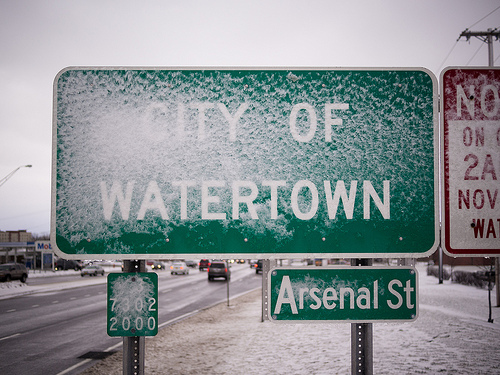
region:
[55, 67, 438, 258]
Snow on the sign.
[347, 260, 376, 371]
Metal post on the ground.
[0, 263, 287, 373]
Paved roads on the ground.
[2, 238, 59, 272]
Gas station in the background.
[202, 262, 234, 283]
Car on the road.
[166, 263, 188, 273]
Red taillights on the car.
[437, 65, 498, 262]
Street sign by the road.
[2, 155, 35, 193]
Light over the street.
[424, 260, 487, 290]
bushes on the ground.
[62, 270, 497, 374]
snow covering the ground.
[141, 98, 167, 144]
the letter C on a snowy sign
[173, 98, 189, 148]
the letter I on a snowy sign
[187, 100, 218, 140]
the letter T on a snowy sign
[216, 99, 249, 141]
the letter Y on a snowy sign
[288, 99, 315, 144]
the letter O on a snowy sign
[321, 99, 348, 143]
the letter F on a snowy sign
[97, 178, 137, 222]
the letter W on a snowy sign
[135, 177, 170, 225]
the letter A on a snowy sign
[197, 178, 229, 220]
the letter E on a snowy sign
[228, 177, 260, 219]
the letter R on a snowy sign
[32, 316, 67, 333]
this is the road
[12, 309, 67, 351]
this is the road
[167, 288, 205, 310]
this is the road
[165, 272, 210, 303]
this is the road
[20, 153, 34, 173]
that is a street light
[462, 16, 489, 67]
that is an electric pole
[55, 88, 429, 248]
that is a road sign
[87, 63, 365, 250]
snow on teh sign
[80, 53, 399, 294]
snow on the streeet sign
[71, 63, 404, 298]
snow on teh green sign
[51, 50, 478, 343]
sign on two pole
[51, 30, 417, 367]
sign on metal poles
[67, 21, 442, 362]
street sign on poles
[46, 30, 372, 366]
street signs on metal poles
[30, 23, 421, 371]
metal poles with street signs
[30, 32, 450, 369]
metal poles with signs